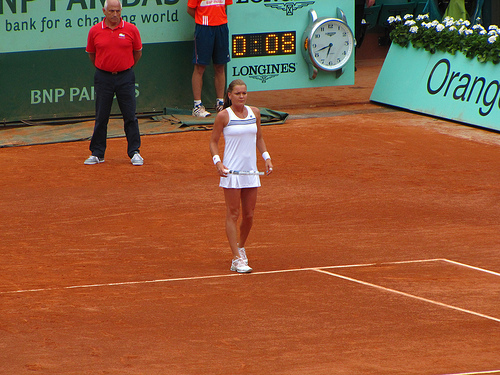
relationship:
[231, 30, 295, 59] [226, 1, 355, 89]
clock on wall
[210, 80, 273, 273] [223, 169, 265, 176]
woman holding racket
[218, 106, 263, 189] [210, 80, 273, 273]
dress on woman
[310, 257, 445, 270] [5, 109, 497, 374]
line on tennis court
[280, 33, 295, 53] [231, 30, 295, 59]
number on clock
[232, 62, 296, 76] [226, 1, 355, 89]
writing on wall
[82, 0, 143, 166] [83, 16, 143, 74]
man wearing shirt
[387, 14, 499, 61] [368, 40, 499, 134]
flowers on wall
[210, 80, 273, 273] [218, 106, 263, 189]
woman wearing dress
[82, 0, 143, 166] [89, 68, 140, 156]
man wearing pants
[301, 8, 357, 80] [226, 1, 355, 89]
analog clock on wall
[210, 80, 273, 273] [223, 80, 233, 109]
woman wearing ponytail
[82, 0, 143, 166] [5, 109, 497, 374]
man standing on tennis court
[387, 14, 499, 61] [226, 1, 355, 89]
flowers on wall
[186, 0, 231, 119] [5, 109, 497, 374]
person standing on tennis court